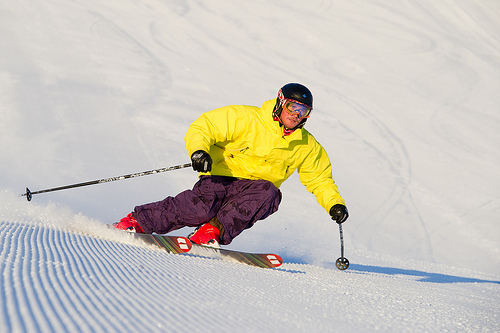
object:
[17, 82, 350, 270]
man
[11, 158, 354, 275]
pair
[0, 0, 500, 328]
ground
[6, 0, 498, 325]
snow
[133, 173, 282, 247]
pants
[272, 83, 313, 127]
helmet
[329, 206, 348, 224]
hand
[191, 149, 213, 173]
hand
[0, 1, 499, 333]
hillside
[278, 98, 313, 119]
goggles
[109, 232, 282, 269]
skis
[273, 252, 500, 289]
shadow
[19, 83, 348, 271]
downhill skier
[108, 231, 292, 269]
turn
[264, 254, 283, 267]
tips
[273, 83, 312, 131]
head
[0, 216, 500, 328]
ripples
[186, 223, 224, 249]
boots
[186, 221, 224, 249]
feet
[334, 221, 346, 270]
pole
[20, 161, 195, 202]
pole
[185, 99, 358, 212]
coat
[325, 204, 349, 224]
gloves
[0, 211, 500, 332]
marks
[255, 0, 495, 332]
right